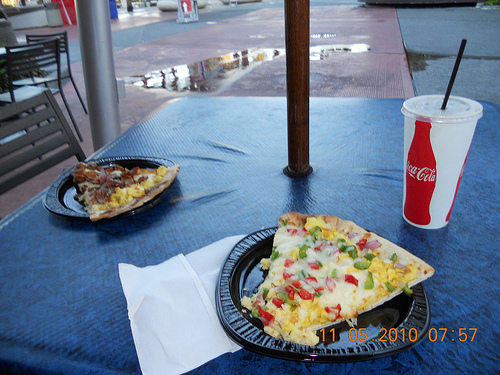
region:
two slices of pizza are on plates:
[47, 127, 447, 366]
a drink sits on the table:
[401, 33, 483, 233]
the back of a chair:
[5, 90, 93, 196]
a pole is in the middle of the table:
[277, 10, 329, 194]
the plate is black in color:
[46, 136, 180, 222]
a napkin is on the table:
[113, 238, 242, 367]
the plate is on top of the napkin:
[209, 228, 281, 364]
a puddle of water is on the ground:
[121, 27, 364, 90]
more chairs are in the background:
[0, 23, 85, 143]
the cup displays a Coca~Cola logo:
[398, 115, 438, 229]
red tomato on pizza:
[297, 286, 314, 301]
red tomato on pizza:
[287, 288, 295, 300]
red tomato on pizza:
[272, 296, 284, 308]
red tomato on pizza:
[256, 302, 277, 327]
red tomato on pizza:
[305, 274, 317, 284]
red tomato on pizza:
[313, 285, 326, 292]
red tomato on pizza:
[322, 277, 335, 291]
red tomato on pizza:
[344, 272, 361, 286]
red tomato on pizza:
[312, 243, 324, 254]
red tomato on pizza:
[288, 229, 297, 237]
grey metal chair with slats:
[4, 102, 93, 200]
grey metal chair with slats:
[7, 42, 77, 120]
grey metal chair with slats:
[27, 26, 84, 93]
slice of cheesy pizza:
[247, 213, 444, 352]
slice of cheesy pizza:
[64, 151, 187, 221]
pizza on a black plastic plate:
[219, 215, 433, 355]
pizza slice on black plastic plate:
[47, 148, 175, 219]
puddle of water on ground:
[136, 37, 372, 102]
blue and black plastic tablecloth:
[8, 70, 496, 372]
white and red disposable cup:
[393, 94, 478, 236]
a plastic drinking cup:
[397, 35, 485, 232]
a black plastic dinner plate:
[215, 226, 432, 357]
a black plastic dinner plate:
[43, 154, 177, 219]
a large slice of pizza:
[252, 212, 434, 333]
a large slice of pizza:
[70, 161, 180, 223]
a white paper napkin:
[116, 232, 248, 373]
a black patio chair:
[0, 91, 88, 193]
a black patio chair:
[7, 38, 85, 140]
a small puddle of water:
[125, 41, 370, 96]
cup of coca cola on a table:
[395, 35, 485, 230]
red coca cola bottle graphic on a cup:
[400, 116, 437, 226]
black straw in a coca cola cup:
[402, 35, 487, 232]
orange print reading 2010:
[373, 325, 418, 346]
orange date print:
[310, 324, 420, 346]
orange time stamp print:
[421, 323, 481, 344]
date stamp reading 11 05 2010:
[312, 321, 419, 348]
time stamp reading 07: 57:
[423, 325, 480, 345]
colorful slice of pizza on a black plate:
[213, 208, 437, 360]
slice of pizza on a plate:
[38, 147, 185, 224]